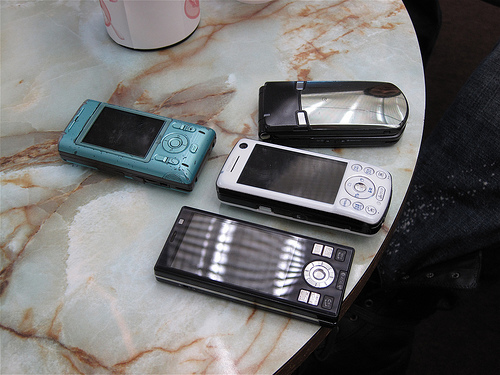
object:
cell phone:
[257, 81, 409, 149]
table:
[1, 0, 500, 374]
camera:
[58, 99, 216, 193]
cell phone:
[215, 138, 392, 237]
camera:
[239, 142, 249, 149]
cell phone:
[153, 206, 355, 331]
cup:
[102, 1, 200, 52]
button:
[312, 243, 324, 256]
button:
[322, 245, 334, 258]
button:
[304, 260, 336, 288]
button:
[298, 289, 310, 304]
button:
[308, 292, 320, 306]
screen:
[236, 143, 348, 205]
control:
[344, 175, 375, 199]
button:
[351, 201, 365, 211]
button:
[339, 197, 352, 208]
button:
[350, 163, 361, 172]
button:
[363, 166, 375, 175]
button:
[376, 186, 387, 201]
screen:
[80, 106, 164, 158]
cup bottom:
[99, 22, 204, 52]